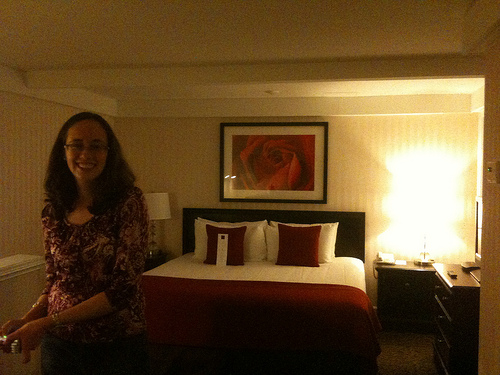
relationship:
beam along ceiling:
[24, 54, 485, 90] [8, 4, 486, 127]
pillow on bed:
[268, 222, 328, 272] [153, 204, 382, 369]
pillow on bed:
[206, 227, 244, 274] [153, 204, 382, 369]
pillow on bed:
[186, 214, 258, 268] [153, 204, 382, 369]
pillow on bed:
[262, 218, 347, 274] [153, 204, 382, 369]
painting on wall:
[215, 118, 332, 208] [113, 125, 471, 297]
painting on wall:
[222, 124, 324, 199] [113, 125, 471, 297]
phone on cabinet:
[377, 244, 395, 265] [375, 265, 431, 329]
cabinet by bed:
[375, 265, 431, 330] [153, 204, 382, 369]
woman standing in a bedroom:
[4, 114, 154, 375] [1, 5, 491, 370]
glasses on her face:
[66, 136, 113, 154] [64, 120, 107, 190]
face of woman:
[64, 120, 107, 190] [4, 114, 154, 368]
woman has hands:
[4, 114, 154, 368] [4, 315, 52, 354]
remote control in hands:
[1, 330, 18, 354] [4, 315, 52, 354]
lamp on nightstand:
[142, 184, 173, 252] [143, 246, 175, 272]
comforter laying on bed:
[135, 270, 377, 370] [153, 204, 382, 369]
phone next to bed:
[377, 250, 395, 264] [153, 204, 382, 369]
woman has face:
[4, 114, 154, 375] [57, 116, 109, 182]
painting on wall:
[222, 124, 324, 199] [150, 107, 405, 208]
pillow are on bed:
[193, 214, 268, 264] [153, 204, 382, 369]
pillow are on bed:
[262, 218, 334, 267] [153, 204, 382, 369]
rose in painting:
[239, 135, 305, 186] [222, 124, 324, 199]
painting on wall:
[222, 124, 324, 199] [153, 118, 404, 212]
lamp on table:
[140, 189, 176, 254] [141, 248, 174, 271]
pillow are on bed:
[193, 214, 268, 264] [139, 200, 380, 373]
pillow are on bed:
[262, 218, 334, 267] [139, 200, 380, 373]